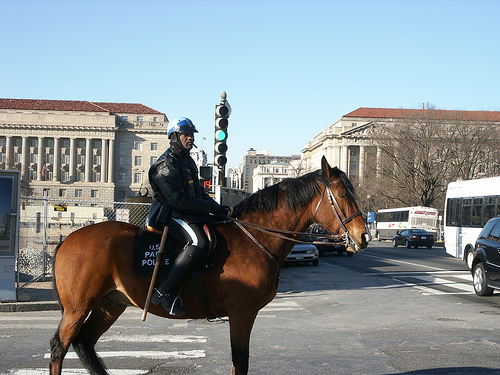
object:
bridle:
[314, 166, 363, 247]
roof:
[0, 98, 108, 114]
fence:
[15, 193, 152, 299]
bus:
[375, 204, 439, 241]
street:
[0, 238, 497, 375]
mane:
[233, 168, 356, 216]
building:
[0, 99, 171, 279]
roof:
[343, 106, 500, 122]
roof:
[91, 102, 162, 114]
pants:
[165, 216, 209, 252]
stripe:
[171, 215, 200, 247]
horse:
[45, 153, 371, 375]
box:
[0, 168, 21, 303]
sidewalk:
[17, 279, 57, 305]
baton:
[140, 225, 171, 322]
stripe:
[414, 210, 436, 215]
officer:
[146, 117, 227, 320]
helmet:
[167, 116, 200, 139]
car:
[391, 229, 436, 250]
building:
[301, 107, 500, 242]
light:
[216, 130, 227, 142]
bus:
[445, 175, 500, 270]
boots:
[149, 244, 204, 317]